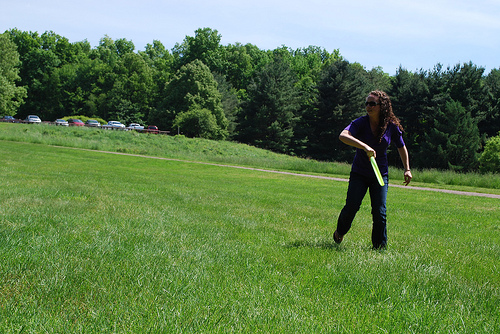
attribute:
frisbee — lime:
[369, 154, 383, 186]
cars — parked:
[8, 101, 149, 139]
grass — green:
[0, 122, 497, 332]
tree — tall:
[154, 62, 238, 145]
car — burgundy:
[142, 125, 163, 136]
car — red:
[67, 116, 88, 126]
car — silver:
[10, 78, 65, 128]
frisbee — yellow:
[368, 154, 390, 189]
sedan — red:
[69, 114, 87, 126]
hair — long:
[367, 85, 406, 142]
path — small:
[4, 137, 498, 199]